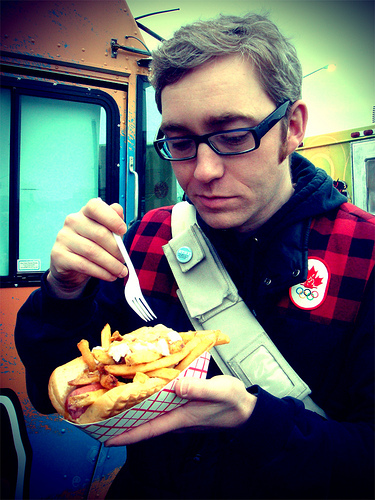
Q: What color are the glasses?
A: Black.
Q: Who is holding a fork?
A: The man.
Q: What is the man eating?
A: Hotdog and fries.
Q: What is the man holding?
A: Food.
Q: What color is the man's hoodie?
A: Blue.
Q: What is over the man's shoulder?
A: A bag strap.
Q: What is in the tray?
A: Hotdog and fries.